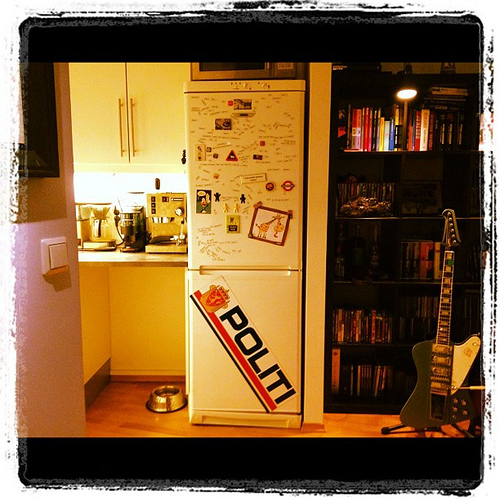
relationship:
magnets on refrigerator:
[197, 93, 303, 252] [176, 76, 310, 431]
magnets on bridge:
[197, 93, 303, 252] [176, 76, 310, 431]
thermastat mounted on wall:
[35, 230, 78, 284] [24, 65, 89, 442]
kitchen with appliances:
[31, 28, 476, 473] [81, 185, 182, 250]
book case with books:
[328, 68, 487, 413] [329, 97, 480, 394]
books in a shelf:
[329, 97, 480, 394] [328, 68, 487, 413]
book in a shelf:
[350, 105, 361, 149] [328, 68, 487, 413]